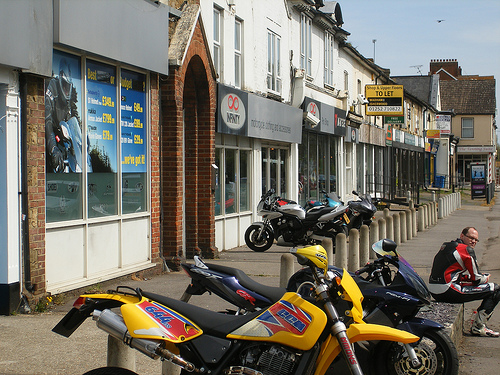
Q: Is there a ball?
A: No, there are no balls.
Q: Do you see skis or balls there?
A: No, there are no balls or skis.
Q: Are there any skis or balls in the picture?
A: No, there are no balls or skis.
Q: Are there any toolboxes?
A: No, there are no toolboxes.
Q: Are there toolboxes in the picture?
A: No, there are no toolboxes.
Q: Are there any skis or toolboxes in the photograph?
A: No, there are no toolboxes or skis.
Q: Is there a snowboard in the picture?
A: No, there are no snowboards.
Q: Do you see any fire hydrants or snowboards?
A: No, there are no snowboards or fire hydrants.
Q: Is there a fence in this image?
A: No, there are no fences.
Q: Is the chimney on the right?
A: Yes, the chimney is on the right of the image.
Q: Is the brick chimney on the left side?
A: No, the chimney is on the right of the image.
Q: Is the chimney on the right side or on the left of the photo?
A: The chimney is on the right of the image.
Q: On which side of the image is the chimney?
A: The chimney is on the right of the image.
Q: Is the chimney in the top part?
A: Yes, the chimney is in the top of the image.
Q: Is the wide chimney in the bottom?
A: No, the chimney is in the top of the image.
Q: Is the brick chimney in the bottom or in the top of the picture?
A: The chimney is in the top of the image.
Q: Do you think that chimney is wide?
A: Yes, the chimney is wide.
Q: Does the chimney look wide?
A: Yes, the chimney is wide.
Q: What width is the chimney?
A: The chimney is wide.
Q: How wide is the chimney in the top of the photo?
A: The chimney is wide.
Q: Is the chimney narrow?
A: No, the chimney is wide.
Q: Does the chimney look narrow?
A: No, the chimney is wide.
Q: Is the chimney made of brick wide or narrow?
A: The chimney is wide.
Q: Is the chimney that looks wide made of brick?
A: Yes, the chimney is made of brick.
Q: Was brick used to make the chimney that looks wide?
A: Yes, the chimney is made of brick.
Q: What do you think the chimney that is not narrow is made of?
A: The chimney is made of brick.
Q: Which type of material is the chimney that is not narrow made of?
A: The chimney is made of brick.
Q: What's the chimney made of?
A: The chimney is made of brick.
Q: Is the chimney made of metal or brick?
A: The chimney is made of brick.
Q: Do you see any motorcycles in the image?
A: Yes, there is a motorcycle.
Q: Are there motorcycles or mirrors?
A: Yes, there is a motorcycle.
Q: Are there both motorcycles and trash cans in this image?
A: No, there is a motorcycle but no trash cans.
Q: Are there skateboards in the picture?
A: No, there are no skateboards.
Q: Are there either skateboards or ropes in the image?
A: No, there are no skateboards or ropes.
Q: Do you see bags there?
A: No, there are no bags.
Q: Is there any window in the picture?
A: Yes, there are windows.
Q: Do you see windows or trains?
A: Yes, there are windows.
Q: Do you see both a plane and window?
A: No, there are windows but no airplanes.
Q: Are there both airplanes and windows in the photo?
A: No, there are windows but no airplanes.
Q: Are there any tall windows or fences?
A: Yes, there are tall windows.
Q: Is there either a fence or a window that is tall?
A: Yes, the windows are tall.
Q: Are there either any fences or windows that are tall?
A: Yes, the windows are tall.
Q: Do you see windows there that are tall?
A: Yes, there are tall windows.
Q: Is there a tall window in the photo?
A: Yes, there are tall windows.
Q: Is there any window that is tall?
A: Yes, there are windows that are tall.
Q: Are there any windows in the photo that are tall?
A: Yes, there are windows that are tall.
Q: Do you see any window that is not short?
A: Yes, there are tall windows.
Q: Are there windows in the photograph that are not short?
A: Yes, there are tall windows.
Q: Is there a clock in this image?
A: No, there are no clocks.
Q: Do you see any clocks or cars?
A: No, there are no clocks or cars.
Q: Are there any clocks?
A: No, there are no clocks.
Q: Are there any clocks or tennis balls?
A: No, there are no clocks or tennis balls.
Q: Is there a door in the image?
A: Yes, there are doors.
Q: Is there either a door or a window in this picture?
A: Yes, there are doors.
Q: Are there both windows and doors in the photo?
A: Yes, there are both doors and windows.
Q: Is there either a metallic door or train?
A: Yes, there are metal doors.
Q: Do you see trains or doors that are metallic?
A: Yes, the doors are metallic.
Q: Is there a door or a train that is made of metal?
A: Yes, the doors are made of metal.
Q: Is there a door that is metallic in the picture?
A: Yes, there are metal doors.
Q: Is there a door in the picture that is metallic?
A: Yes, there are doors that are metallic.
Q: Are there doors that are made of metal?
A: Yes, there are doors that are made of metal.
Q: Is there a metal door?
A: Yes, there are doors that are made of metal.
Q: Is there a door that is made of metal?
A: Yes, there are doors that are made of metal.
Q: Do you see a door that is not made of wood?
A: Yes, there are doors that are made of metal.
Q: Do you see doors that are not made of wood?
A: Yes, there are doors that are made of metal.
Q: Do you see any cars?
A: No, there are no cars.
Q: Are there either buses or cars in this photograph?
A: No, there are no cars or buses.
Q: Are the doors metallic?
A: Yes, the doors are metallic.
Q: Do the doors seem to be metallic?
A: Yes, the doors are metallic.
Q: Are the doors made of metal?
A: Yes, the doors are made of metal.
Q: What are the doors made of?
A: The doors are made of metal.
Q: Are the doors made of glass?
A: No, the doors are made of metal.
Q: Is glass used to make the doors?
A: No, the doors are made of metal.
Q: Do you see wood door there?
A: No, there are doors but they are made of metal.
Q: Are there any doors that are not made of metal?
A: No, there are doors but they are made of metal.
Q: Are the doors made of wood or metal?
A: The doors are made of metal.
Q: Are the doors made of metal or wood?
A: The doors are made of metal.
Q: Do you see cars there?
A: No, there are no cars.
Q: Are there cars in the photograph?
A: No, there are no cars.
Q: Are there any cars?
A: No, there are no cars.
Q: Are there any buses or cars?
A: No, there are no cars or buses.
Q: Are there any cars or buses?
A: No, there are no cars or buses.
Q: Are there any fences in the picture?
A: No, there are no fences.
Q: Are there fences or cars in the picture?
A: No, there are no fences or cars.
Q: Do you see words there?
A: Yes, there are words.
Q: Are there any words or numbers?
A: Yes, there are words.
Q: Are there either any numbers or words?
A: Yes, there are words.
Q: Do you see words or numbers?
A: Yes, there are words.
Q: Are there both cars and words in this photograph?
A: No, there are words but no cars.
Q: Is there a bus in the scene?
A: No, there are no buses.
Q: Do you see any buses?
A: No, there are no buses.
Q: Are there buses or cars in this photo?
A: No, there are no buses or cars.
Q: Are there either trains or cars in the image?
A: No, there are no cars or trains.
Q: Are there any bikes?
A: Yes, there is a bike.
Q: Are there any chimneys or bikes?
A: Yes, there is a bike.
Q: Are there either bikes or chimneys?
A: Yes, there is a bike.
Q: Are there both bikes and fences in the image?
A: No, there is a bike but no fences.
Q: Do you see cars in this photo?
A: No, there are no cars.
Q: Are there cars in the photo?
A: No, there are no cars.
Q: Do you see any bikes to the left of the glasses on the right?
A: Yes, there is a bike to the left of the glasses.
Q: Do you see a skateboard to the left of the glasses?
A: No, there is a bike to the left of the glasses.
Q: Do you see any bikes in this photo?
A: Yes, there is a bike.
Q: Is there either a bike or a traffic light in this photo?
A: Yes, there is a bike.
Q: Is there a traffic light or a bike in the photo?
A: Yes, there is a bike.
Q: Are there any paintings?
A: No, there are no paintings.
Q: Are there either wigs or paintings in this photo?
A: No, there are no paintings or wigs.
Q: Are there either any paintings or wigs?
A: No, there are no paintings or wigs.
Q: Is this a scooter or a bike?
A: This is a bike.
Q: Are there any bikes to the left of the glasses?
A: Yes, there is a bike to the left of the glasses.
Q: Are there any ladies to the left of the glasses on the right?
A: No, there is a bike to the left of the glasses.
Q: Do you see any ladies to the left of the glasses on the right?
A: No, there is a bike to the left of the glasses.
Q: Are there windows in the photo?
A: Yes, there is a window.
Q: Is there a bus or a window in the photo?
A: Yes, there is a window.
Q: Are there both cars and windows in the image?
A: No, there is a window but no cars.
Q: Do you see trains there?
A: No, there are no trains.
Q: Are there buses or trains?
A: No, there are no trains or buses.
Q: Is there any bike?
A: Yes, there is a bike.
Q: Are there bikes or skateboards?
A: Yes, there is a bike.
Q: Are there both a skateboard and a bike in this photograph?
A: No, there is a bike but no skateboards.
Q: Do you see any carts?
A: No, there are no carts.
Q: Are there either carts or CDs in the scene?
A: No, there are no carts or cds.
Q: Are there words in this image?
A: Yes, there are words.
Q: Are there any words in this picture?
A: Yes, there are words.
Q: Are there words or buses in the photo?
A: Yes, there are words.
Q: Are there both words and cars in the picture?
A: No, there are words but no cars.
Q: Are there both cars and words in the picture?
A: No, there are words but no cars.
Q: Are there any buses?
A: No, there are no buses.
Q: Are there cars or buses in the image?
A: No, there are no buses or cars.